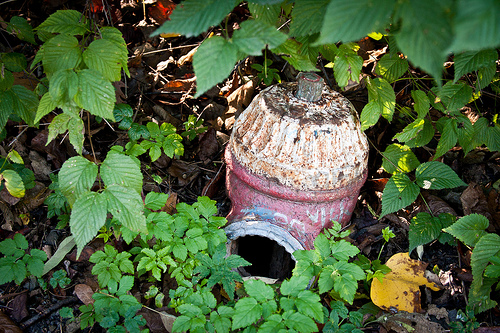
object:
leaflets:
[155, 56, 181, 75]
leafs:
[192, 36, 238, 98]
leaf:
[192, 36, 237, 99]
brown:
[227, 80, 255, 105]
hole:
[231, 233, 296, 285]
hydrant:
[224, 73, 370, 285]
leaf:
[407, 213, 440, 256]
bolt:
[294, 71, 325, 102]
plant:
[0, 233, 50, 290]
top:
[227, 70, 369, 191]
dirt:
[263, 89, 304, 118]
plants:
[53, 293, 153, 333]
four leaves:
[67, 190, 108, 261]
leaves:
[307, 0, 398, 49]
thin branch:
[368, 140, 434, 216]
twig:
[87, 112, 97, 164]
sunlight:
[389, 144, 429, 177]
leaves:
[442, 0, 500, 56]